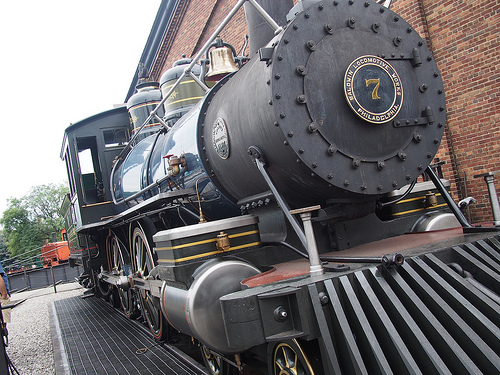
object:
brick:
[456, 135, 466, 141]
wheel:
[133, 227, 168, 341]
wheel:
[111, 237, 137, 319]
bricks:
[479, 68, 489, 75]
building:
[122, 1, 500, 236]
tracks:
[95, 297, 211, 375]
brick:
[465, 154, 475, 159]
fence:
[6, 265, 57, 293]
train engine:
[59, 0, 500, 375]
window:
[102, 127, 129, 147]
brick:
[448, 58, 452, 62]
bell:
[205, 35, 240, 78]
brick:
[458, 123, 469, 129]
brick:
[472, 105, 483, 112]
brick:
[462, 127, 467, 131]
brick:
[458, 79, 462, 84]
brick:
[438, 20, 448, 27]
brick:
[438, 61, 443, 66]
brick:
[442, 79, 449, 84]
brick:
[485, 80, 496, 86]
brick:
[473, 53, 484, 61]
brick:
[473, 84, 484, 90]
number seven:
[364, 77, 381, 99]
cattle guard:
[306, 235, 499, 375]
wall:
[157, 0, 500, 223]